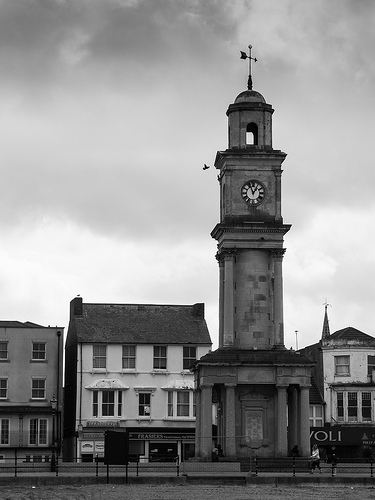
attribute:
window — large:
[90, 390, 121, 416]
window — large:
[181, 341, 198, 371]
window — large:
[90, 343, 108, 369]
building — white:
[301, 298, 373, 453]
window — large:
[84, 337, 116, 370]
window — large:
[0, 342, 7, 359]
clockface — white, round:
[241, 177, 265, 204]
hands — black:
[248, 184, 254, 195]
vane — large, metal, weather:
[240, 42, 258, 92]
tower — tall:
[171, 49, 319, 481]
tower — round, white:
[208, 29, 369, 418]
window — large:
[135, 389, 153, 420]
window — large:
[152, 345, 176, 373]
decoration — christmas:
[316, 297, 339, 337]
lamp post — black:
[46, 390, 59, 471]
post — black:
[285, 443, 307, 478]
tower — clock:
[194, 46, 314, 463]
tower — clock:
[192, 80, 325, 473]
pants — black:
[312, 458, 322, 469]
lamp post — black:
[47, 395, 58, 473]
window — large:
[160, 373, 200, 428]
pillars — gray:
[194, 381, 318, 466]